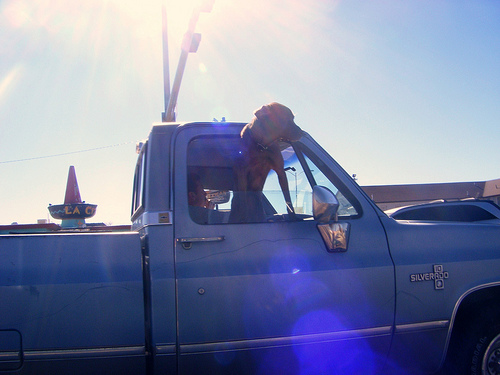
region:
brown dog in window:
[142, 95, 393, 256]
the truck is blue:
[1, 105, 492, 370]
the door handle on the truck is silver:
[156, 221, 231, 261]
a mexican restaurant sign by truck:
[37, 151, 108, 227]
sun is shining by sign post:
[1, 3, 358, 134]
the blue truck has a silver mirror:
[294, 182, 362, 259]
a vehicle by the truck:
[377, 190, 498, 227]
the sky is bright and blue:
[2, 2, 499, 207]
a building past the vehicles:
[332, 176, 499, 216]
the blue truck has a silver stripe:
[0, 317, 452, 365]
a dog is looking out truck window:
[223, 95, 315, 229]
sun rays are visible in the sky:
[4, 2, 317, 92]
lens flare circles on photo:
[226, 91, 368, 374]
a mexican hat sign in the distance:
[47, 160, 100, 222]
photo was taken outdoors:
[1, 1, 498, 369]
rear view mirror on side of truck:
[308, 185, 351, 255]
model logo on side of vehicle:
[404, 260, 454, 298]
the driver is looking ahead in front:
[180, 172, 221, 227]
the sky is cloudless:
[3, 6, 493, 176]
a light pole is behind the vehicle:
[154, 3, 215, 128]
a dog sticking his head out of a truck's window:
[235, 100, 305, 218]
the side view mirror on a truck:
[306, 186, 351, 253]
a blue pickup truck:
[0, 117, 498, 374]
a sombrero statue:
[46, 162, 102, 231]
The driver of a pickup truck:
[186, 175, 230, 222]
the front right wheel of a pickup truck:
[446, 284, 498, 374]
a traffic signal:
[157, 2, 209, 121]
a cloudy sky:
[5, 5, 498, 177]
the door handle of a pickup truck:
[176, 235, 226, 250]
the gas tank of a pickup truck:
[0, 331, 24, 373]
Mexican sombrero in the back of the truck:
[46, 163, 96, 220]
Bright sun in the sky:
[16, 6, 323, 49]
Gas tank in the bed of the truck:
[5, 318, 29, 370]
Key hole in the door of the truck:
[191, 286, 208, 298]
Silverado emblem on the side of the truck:
[405, 264, 456, 286]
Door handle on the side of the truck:
[171, 230, 231, 247]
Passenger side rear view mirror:
[305, 181, 353, 258]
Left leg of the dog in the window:
[269, 163, 297, 217]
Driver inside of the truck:
[185, 173, 212, 210]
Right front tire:
[461, 321, 496, 373]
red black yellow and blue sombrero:
[51, 164, 101, 220]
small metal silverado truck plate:
[395, 257, 448, 289]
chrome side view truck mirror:
[310, 184, 353, 247]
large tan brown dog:
[237, 105, 299, 220]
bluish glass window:
[187, 188, 348, 223]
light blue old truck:
[1, 119, 498, 372]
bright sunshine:
[5, 2, 312, 114]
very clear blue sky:
[1, 2, 496, 235]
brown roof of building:
[350, 177, 497, 217]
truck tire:
[464, 317, 499, 371]